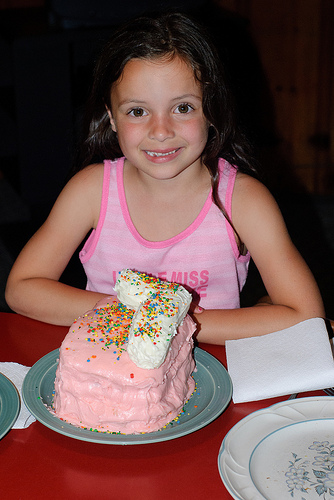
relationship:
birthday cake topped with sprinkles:
[51, 265, 198, 435] [103, 298, 135, 350]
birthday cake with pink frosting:
[51, 265, 198, 435] [50, 293, 197, 435]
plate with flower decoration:
[211, 395, 333, 499] [284, 433, 330, 498]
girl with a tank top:
[4, 15, 326, 344] [73, 154, 255, 313]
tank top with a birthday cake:
[73, 154, 255, 313] [51, 265, 198, 435]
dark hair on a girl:
[76, 11, 267, 259] [4, 15, 326, 344]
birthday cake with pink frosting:
[51, 265, 198, 435] [61, 312, 125, 426]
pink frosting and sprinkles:
[61, 312, 125, 426] [102, 294, 178, 347]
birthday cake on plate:
[51, 265, 198, 435] [21, 347, 233, 443]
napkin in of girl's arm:
[225, 317, 332, 401] [194, 174, 323, 340]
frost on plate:
[51, 270, 195, 432] [25, 340, 231, 445]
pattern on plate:
[279, 444, 333, 499] [218, 397, 330, 498]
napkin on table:
[225, 317, 333, 405] [0, 313, 333, 498]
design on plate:
[287, 433, 331, 496] [211, 395, 333, 499]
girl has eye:
[0, 15, 327, 342] [123, 104, 152, 117]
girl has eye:
[0, 15, 327, 342] [173, 101, 196, 115]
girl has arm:
[0, 15, 327, 342] [4, 164, 203, 350]